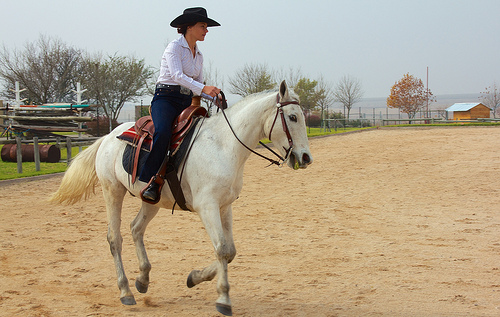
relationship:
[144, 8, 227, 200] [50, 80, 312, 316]
person on top of horse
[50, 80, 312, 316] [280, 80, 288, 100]
horse has ear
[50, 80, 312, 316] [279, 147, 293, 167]
horse has bit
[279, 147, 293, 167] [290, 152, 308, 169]
bit inside of mouth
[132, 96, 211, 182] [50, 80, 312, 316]
saddle on top of horse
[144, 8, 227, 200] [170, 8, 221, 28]
woman has hat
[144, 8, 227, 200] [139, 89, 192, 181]
woman wearing jeans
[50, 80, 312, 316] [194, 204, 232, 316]
horse has front leg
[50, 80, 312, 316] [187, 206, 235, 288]
horse has front leg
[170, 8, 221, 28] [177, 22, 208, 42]
hat on top of head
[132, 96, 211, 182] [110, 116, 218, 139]
saddle on top of back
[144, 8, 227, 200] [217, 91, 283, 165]
person holding reins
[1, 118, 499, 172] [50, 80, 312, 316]
fence behind horse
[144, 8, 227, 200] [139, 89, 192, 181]
person wearing pants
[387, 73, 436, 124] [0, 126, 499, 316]
tree next to field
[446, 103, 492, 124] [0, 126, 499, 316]
low building next to field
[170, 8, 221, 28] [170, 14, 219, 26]
hat has brim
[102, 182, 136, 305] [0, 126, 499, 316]
leg above field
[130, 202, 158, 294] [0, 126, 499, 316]
leg above field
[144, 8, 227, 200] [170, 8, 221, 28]
person has hat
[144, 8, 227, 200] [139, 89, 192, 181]
woman has jeans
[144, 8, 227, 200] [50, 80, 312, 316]
woman riding horse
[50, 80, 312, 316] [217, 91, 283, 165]
horse has reins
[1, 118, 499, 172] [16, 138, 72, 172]
fence has section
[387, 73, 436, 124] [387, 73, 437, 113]
tree has fall leaves